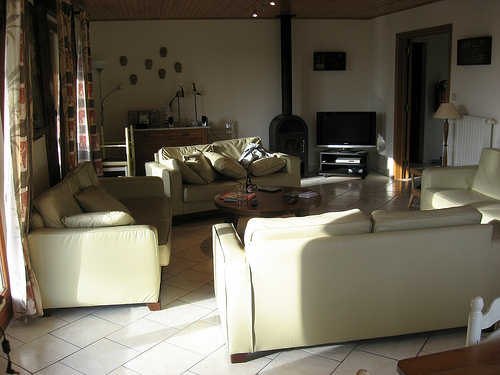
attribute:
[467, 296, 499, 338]
chair back — white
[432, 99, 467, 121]
lampshade — white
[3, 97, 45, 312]
curtains — floral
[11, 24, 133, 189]
curtains — multicolored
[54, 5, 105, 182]
curtain — multicolored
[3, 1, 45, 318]
curtain — multicolored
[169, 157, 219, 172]
cushion — white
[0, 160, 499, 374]
tiles — white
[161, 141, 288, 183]
pillows — messy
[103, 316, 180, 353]
tile — white, polished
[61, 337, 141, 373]
tile — white, polished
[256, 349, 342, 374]
tile — white, polished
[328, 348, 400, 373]
tile — white, polished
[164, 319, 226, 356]
tile — white, polished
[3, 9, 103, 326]
curtains — decorative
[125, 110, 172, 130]
stereo — small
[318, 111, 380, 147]
tv — flatscreen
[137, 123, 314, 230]
sofa — white